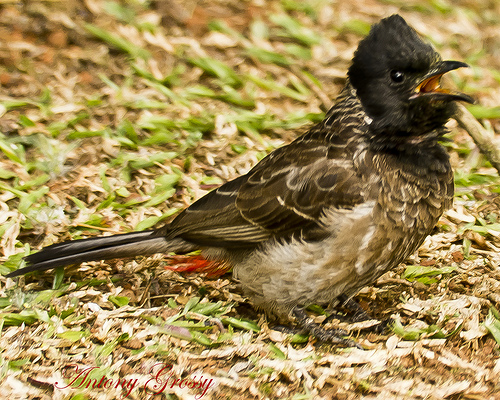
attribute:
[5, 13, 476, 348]
bird — small, short, thin, brown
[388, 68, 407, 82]
eye — black, small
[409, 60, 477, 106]
beak — small, open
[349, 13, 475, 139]
head — black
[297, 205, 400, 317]
stomach — gray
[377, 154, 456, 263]
chest — brown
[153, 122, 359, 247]
wing — brown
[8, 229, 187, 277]
feathers — dark, black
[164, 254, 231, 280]
feathers — red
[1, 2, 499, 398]
grass — green, brown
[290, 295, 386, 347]
feet — black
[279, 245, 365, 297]
feathers — white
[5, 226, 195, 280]
tail — long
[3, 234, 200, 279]
feather — long, brown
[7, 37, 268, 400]
leaves — green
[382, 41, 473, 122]
face — black